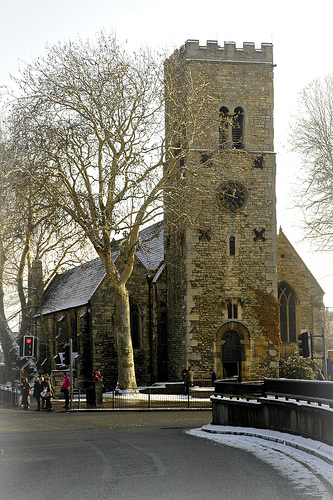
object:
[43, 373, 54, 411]
person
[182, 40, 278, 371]
wall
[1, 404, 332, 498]
intersection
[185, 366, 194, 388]
person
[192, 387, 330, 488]
snow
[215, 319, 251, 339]
arch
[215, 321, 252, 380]
entrance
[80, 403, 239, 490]
track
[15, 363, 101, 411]
pedestrians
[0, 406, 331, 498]
road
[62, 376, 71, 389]
coat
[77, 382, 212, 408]
fence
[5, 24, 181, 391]
tree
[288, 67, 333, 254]
tree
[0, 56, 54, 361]
tree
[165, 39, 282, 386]
building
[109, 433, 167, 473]
line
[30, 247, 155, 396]
building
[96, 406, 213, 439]
street corner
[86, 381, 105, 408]
trash container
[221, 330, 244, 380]
door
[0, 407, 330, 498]
street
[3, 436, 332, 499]
ground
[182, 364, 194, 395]
person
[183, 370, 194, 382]
brown coat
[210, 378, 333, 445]
fence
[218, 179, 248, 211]
clock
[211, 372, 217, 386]
coat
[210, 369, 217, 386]
person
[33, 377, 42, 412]
person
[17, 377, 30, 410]
person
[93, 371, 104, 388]
person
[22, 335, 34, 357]
light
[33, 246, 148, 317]
roof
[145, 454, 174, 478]
part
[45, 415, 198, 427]
edge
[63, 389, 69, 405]
pants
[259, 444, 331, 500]
tire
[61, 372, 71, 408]
person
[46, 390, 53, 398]
bag